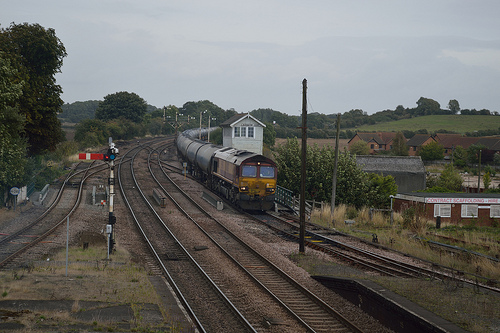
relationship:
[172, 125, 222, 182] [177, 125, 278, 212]
tanks on train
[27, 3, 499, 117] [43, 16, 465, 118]
cloud in sky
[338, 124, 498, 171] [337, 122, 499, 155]
buildings with roofs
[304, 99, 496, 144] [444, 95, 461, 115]
hilltop enclosed with trees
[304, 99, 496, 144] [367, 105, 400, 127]
hilltop enclosed with shrubs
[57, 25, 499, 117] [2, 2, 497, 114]
cloud in sky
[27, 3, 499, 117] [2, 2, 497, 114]
cloud in sky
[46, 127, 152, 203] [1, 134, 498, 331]
edge on train tracks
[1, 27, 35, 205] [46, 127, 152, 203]
tree along edge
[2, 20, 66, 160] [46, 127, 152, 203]
tree along edge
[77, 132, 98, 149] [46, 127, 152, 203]
tree along edge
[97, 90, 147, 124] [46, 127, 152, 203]
tree along edge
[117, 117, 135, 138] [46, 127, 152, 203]
tree along edge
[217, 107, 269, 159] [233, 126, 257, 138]
building with windows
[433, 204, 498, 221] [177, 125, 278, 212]
windows on train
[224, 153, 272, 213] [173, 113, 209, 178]
engine leading train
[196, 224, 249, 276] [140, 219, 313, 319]
gravel on tracks